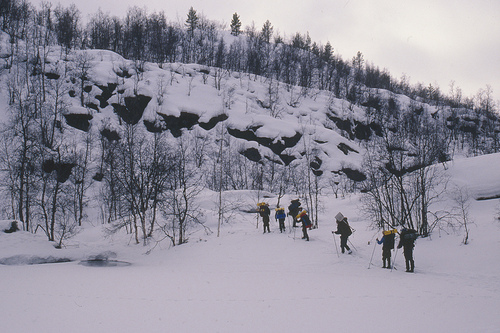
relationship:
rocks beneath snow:
[69, 84, 304, 154] [57, 45, 346, 161]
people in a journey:
[256, 194, 421, 275] [1, 17, 497, 333]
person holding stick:
[328, 209, 362, 257] [330, 230, 345, 258]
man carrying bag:
[393, 223, 422, 276] [399, 227, 421, 247]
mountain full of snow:
[6, 4, 493, 177] [1, 17, 497, 333]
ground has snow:
[3, 193, 499, 333] [1, 17, 497, 333]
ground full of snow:
[3, 193, 499, 333] [1, 17, 497, 333]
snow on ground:
[1, 17, 497, 333] [3, 193, 499, 333]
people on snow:
[256, 194, 421, 275] [1, 17, 497, 333]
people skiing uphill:
[256, 194, 421, 275] [1, 17, 497, 333]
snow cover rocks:
[1, 17, 497, 333] [69, 84, 304, 154]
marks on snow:
[416, 262, 488, 299] [1, 17, 497, 333]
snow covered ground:
[1, 17, 497, 333] [3, 193, 499, 333]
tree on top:
[183, 4, 200, 36] [92, 9, 366, 81]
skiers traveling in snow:
[256, 194, 421, 275] [1, 17, 497, 333]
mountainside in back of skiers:
[6, 4, 493, 177] [256, 194, 421, 275]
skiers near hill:
[256, 194, 421, 275] [6, 4, 493, 177]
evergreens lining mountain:
[5, 1, 489, 110] [6, 4, 493, 177]